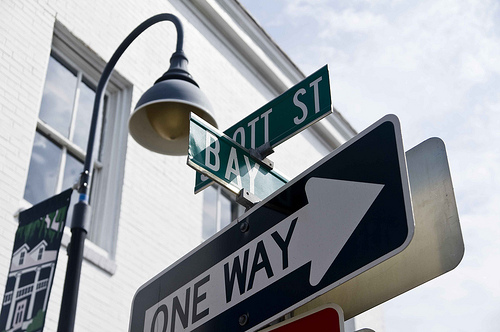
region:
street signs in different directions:
[188, 118, 300, 182]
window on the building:
[61, 60, 103, 224]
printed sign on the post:
[11, 203, 60, 330]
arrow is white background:
[166, 183, 365, 307]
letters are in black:
[167, 229, 288, 320]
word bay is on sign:
[182, 144, 285, 196]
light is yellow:
[156, 101, 181, 145]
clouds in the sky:
[322, 10, 486, 102]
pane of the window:
[51, 65, 71, 130]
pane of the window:
[28, 141, 52, 203]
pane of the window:
[62, 162, 97, 230]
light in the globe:
[159, 111, 200, 146]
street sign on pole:
[232, 78, 334, 146]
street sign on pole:
[161, 209, 390, 296]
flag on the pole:
[1, 188, 78, 329]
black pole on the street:
[73, 201, 91, 328]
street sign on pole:
[188, 130, 278, 201]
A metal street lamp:
[70, 5, 260, 174]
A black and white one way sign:
[118, 101, 495, 330]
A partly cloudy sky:
[340, 12, 464, 93]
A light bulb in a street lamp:
[140, 103, 199, 148]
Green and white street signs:
[142, 60, 382, 197]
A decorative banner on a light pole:
[0, 178, 97, 330]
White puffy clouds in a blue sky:
[297, 8, 496, 85]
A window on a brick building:
[19, 7, 141, 283]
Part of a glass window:
[34, 58, 104, 150]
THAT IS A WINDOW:
[37, 262, 57, 285]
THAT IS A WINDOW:
[31, 289, 43, 316]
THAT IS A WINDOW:
[19, 265, 35, 285]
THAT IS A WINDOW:
[9, 296, 29, 319]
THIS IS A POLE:
[63, 198, 84, 265]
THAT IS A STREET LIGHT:
[130, 72, 212, 144]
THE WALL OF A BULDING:
[155, 198, 183, 231]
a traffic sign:
[186, 235, 318, 300]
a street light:
[127, 76, 186, 128]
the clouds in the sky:
[341, 20, 484, 107]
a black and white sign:
[256, 198, 379, 267]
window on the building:
[42, 63, 82, 146]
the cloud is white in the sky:
[367, 20, 474, 87]